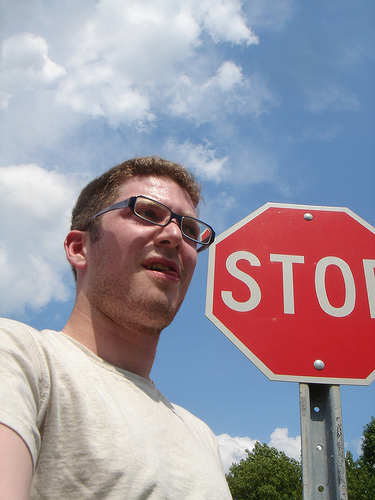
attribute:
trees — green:
[224, 414, 373, 499]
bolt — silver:
[313, 358, 323, 370]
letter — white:
[218, 248, 262, 312]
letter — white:
[268, 252, 305, 315]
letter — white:
[312, 254, 355, 318]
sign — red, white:
[205, 203, 374, 388]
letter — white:
[360, 257, 373, 322]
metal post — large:
[296, 381, 347, 498]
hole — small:
[311, 404, 321, 416]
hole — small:
[314, 443, 322, 453]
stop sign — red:
[203, 202, 374, 385]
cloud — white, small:
[301, 83, 362, 119]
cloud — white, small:
[265, 426, 301, 464]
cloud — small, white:
[213, 430, 260, 477]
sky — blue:
[1, 2, 373, 477]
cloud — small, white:
[0, 247, 70, 321]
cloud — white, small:
[1, 30, 66, 109]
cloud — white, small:
[54, 62, 156, 136]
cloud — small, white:
[68, 31, 140, 53]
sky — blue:
[237, 44, 373, 169]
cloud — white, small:
[85, 36, 148, 68]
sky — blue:
[217, 54, 344, 132]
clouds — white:
[80, 34, 220, 130]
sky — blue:
[74, 38, 296, 115]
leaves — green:
[252, 448, 279, 460]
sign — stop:
[207, 187, 372, 358]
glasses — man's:
[124, 184, 223, 246]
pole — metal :
[292, 373, 362, 499]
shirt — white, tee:
[19, 326, 230, 499]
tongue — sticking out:
[161, 269, 182, 277]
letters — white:
[222, 251, 373, 317]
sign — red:
[208, 191, 373, 394]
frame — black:
[123, 194, 141, 210]